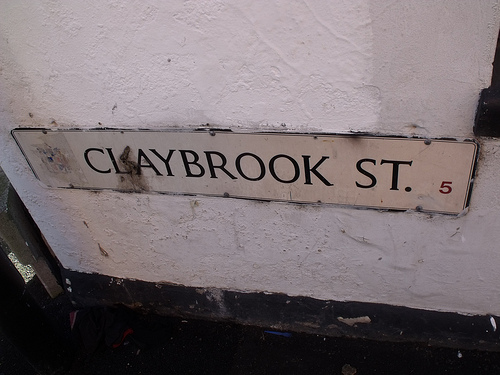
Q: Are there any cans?
A: No, there are no cans.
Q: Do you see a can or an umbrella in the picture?
A: No, there are no cans or umbrellas.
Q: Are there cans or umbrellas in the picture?
A: No, there are no cans or umbrellas.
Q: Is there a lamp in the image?
A: No, there are no lamps.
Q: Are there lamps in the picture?
A: No, there are no lamps.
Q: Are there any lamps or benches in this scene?
A: No, there are no lamps or benches.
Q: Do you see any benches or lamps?
A: No, there are no lamps or benches.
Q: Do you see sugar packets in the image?
A: No, there are no sugar packets.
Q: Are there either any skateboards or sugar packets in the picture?
A: No, there are no sugar packets or skateboards.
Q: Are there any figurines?
A: No, there are no figurines.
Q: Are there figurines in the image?
A: No, there are no figurines.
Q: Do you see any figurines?
A: No, there are no figurines.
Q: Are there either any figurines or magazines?
A: No, there are no figurines or magazines.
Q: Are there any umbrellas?
A: No, there are no umbrellas.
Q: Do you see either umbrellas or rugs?
A: No, there are no umbrellas or rugs.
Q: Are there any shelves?
A: No, there are no shelves.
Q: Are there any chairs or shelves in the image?
A: No, there are no shelves or chairs.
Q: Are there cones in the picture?
A: No, there are no cones.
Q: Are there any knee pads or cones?
A: No, there are no cones or knee pads.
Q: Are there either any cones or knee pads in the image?
A: No, there are no cones or knee pads.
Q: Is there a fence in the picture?
A: No, there are no fences.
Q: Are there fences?
A: No, there are no fences.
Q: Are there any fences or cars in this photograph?
A: No, there are no fences or cars.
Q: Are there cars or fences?
A: No, there are no fences or cars.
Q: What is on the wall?
A: The sign is on the wall.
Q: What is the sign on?
A: The sign is on the wall.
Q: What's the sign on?
A: The sign is on the wall.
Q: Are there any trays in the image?
A: No, there are no trays.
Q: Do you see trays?
A: No, there are no trays.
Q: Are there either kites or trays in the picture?
A: No, there are no trays or kites.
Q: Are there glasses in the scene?
A: No, there are no glasses.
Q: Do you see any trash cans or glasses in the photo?
A: No, there are no glasses or trash cans.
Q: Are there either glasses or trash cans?
A: No, there are no glasses or trash cans.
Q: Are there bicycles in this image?
A: No, there are no bicycles.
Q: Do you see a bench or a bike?
A: No, there are no bikes or benches.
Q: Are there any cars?
A: No, there are no cars.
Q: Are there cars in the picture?
A: No, there are no cars.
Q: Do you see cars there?
A: No, there are no cars.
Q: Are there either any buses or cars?
A: No, there are no cars or buses.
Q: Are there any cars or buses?
A: No, there are no cars or buses.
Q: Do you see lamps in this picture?
A: No, there are no lamps.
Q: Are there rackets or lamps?
A: No, there are no lamps or rackets.